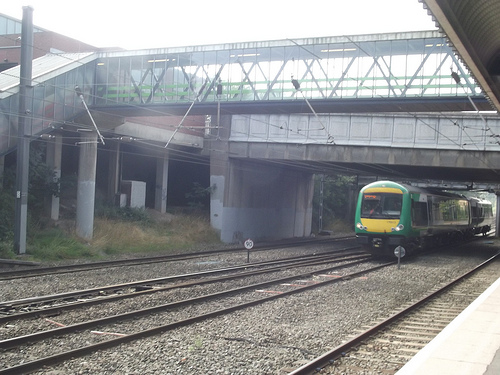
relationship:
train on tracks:
[350, 177, 496, 253] [0, 238, 500, 374]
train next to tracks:
[350, 177, 496, 253] [0, 238, 500, 374]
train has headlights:
[350, 177, 496, 253] [357, 221, 403, 234]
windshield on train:
[360, 189, 406, 224] [350, 177, 496, 253]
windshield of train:
[360, 189, 406, 224] [350, 177, 496, 253]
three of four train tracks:
[1, 235, 293, 373] [0, 238, 500, 374]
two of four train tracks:
[1, 244, 70, 326] [0, 238, 500, 374]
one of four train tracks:
[300, 288, 499, 371] [0, 238, 500, 374]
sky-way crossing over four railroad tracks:
[96, 50, 462, 108] [0, 238, 500, 374]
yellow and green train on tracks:
[350, 177, 496, 253] [0, 238, 500, 374]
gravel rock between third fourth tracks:
[192, 324, 288, 372] [404, 252, 500, 374]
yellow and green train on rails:
[359, 220, 402, 230] [350, 177, 496, 253]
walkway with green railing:
[96, 50, 462, 108] [93, 72, 485, 101]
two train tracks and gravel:
[283, 267, 500, 374] [192, 324, 288, 372]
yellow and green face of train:
[360, 185, 403, 230] [350, 177, 496, 253]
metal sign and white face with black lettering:
[243, 237, 256, 264] [245, 241, 255, 247]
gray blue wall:
[210, 206, 312, 238] [210, 163, 316, 235]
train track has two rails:
[350, 177, 496, 253] [1, 321, 498, 374]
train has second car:
[350, 177, 496, 253] [470, 196, 498, 238]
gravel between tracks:
[192, 324, 288, 372] [0, 238, 500, 374]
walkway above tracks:
[96, 50, 462, 108] [0, 238, 500, 374]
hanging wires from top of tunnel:
[1, 109, 499, 180] [234, 158, 498, 247]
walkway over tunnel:
[96, 50, 462, 108] [234, 158, 498, 247]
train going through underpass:
[350, 177, 496, 253] [234, 158, 498, 247]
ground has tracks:
[192, 324, 288, 372] [0, 238, 500, 374]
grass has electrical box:
[96, 198, 212, 251] [112, 177, 149, 213]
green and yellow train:
[401, 189, 418, 238] [350, 177, 496, 253]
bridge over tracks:
[96, 50, 462, 108] [0, 238, 500, 374]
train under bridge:
[350, 177, 496, 253] [96, 50, 462, 108]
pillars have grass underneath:
[46, 127, 104, 244] [29, 227, 77, 261]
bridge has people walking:
[96, 50, 462, 108] [211, 69, 464, 100]